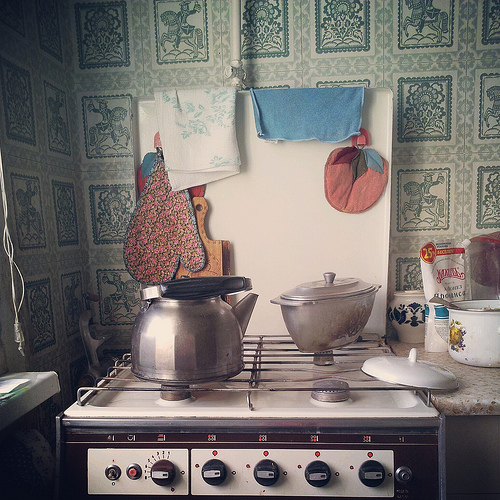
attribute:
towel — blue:
[253, 97, 355, 137]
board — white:
[138, 91, 388, 328]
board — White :
[146, 105, 403, 341]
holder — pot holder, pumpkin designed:
[324, 126, 391, 216]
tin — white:
[385, 285, 427, 345]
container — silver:
[270, 272, 385, 352]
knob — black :
[201, 460, 228, 486]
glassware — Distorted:
[278, 269, 387, 350]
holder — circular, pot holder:
[286, 115, 407, 217]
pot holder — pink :
[324, 132, 395, 217]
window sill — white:
[2, 366, 65, 427]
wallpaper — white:
[386, 25, 476, 156]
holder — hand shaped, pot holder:
[123, 165, 198, 267]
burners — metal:
[90, 285, 430, 421]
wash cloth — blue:
[251, 86, 366, 146]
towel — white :
[125, 57, 242, 214]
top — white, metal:
[360, 338, 464, 391]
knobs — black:
[204, 452, 386, 492]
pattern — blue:
[388, 298, 421, 328]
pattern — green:
[220, 0, 378, 68]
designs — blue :
[341, 133, 389, 184]